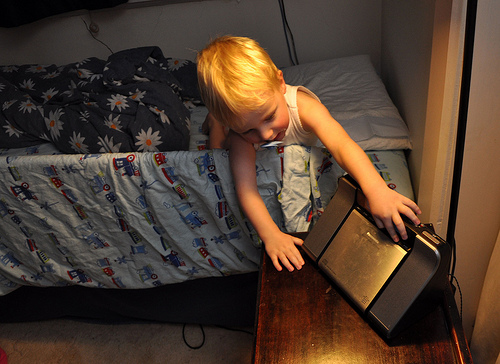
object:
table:
[254, 240, 474, 364]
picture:
[0, 24, 500, 332]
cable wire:
[278, 0, 301, 66]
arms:
[228, 90, 423, 273]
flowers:
[106, 93, 130, 113]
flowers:
[134, 126, 163, 152]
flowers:
[97, 134, 123, 153]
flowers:
[66, 130, 90, 153]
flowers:
[43, 107, 90, 140]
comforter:
[0, 45, 339, 297]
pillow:
[279, 54, 415, 152]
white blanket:
[61, 188, 79, 204]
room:
[0, 0, 499, 364]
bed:
[0, 54, 413, 329]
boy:
[197, 33, 421, 271]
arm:
[296, 91, 421, 243]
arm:
[230, 131, 306, 273]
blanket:
[0, 140, 416, 298]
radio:
[300, 176, 451, 347]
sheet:
[0, 102, 415, 297]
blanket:
[0, 45, 204, 154]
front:
[0, 145, 500, 308]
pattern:
[95, 88, 162, 153]